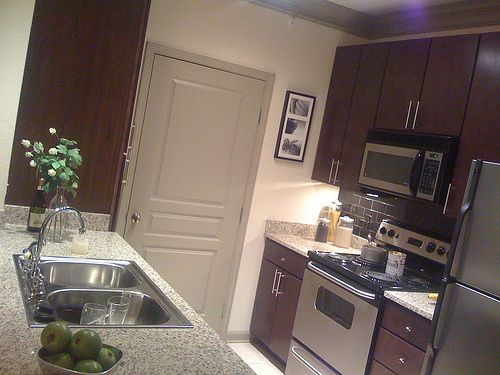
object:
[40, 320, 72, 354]
apple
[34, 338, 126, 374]
bowl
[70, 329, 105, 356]
apple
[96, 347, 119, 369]
apple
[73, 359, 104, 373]
apple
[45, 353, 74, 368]
apple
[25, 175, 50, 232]
bottle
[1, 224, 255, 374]
counter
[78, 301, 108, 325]
glass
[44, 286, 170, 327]
sink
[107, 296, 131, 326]
glass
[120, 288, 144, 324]
glass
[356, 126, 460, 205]
microwave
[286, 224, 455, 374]
stove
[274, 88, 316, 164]
picture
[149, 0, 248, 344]
wall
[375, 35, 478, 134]
cupboard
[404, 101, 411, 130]
handle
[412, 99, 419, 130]
handle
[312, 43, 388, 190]
cupboard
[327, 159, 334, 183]
handle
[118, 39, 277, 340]
door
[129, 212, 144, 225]
knob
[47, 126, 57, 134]
flower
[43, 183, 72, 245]
vase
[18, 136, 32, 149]
flower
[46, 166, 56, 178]
flower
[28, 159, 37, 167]
flower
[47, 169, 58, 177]
rose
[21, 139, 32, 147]
rose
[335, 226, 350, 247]
jar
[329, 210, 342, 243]
pasta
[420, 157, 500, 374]
fridge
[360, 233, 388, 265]
pot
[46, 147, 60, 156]
flower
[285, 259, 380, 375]
face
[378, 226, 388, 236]
dial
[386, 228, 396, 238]
dial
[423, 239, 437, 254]
dial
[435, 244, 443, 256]
dial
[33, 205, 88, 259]
faucet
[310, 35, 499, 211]
cabinets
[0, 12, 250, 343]
wall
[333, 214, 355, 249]
jar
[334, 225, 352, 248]
food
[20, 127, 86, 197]
plant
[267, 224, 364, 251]
counter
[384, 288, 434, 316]
counter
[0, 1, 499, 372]
kitchen